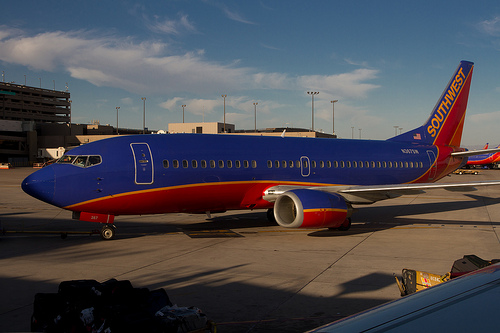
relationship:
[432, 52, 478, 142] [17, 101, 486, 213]
tail on plane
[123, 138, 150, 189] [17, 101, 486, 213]
door on plane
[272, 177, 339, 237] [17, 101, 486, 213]
engine on plane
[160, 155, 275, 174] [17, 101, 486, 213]
windows on plane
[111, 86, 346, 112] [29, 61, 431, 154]
lights at airport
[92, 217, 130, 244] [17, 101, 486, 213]
wheels on plane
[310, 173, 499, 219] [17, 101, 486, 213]
wing on jet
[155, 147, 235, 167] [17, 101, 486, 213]
window on plane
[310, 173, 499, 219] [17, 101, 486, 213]
wing on plane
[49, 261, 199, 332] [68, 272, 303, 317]
luggage in shade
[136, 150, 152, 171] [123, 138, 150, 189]
part of door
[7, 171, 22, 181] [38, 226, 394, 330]
part of runway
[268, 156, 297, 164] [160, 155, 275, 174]
section of windows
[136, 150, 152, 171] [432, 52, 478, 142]
part of tail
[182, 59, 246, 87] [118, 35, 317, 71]
part of cloud